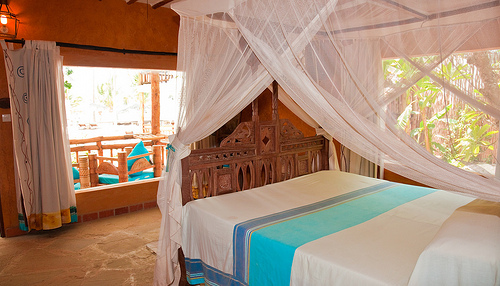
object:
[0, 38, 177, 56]
curtain rod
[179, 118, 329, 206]
foot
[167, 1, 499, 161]
curtins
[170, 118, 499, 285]
bed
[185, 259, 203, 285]
frame